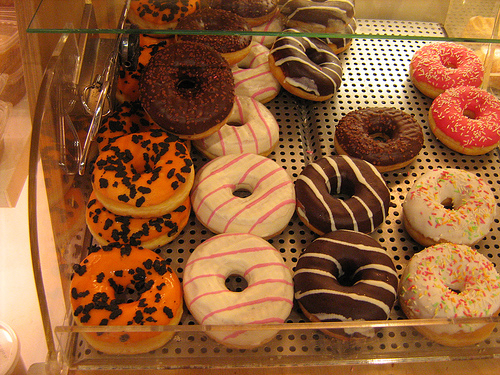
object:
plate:
[0, 324, 20, 374]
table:
[77, 4, 119, 112]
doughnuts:
[189, 152, 295, 240]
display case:
[27, 0, 500, 375]